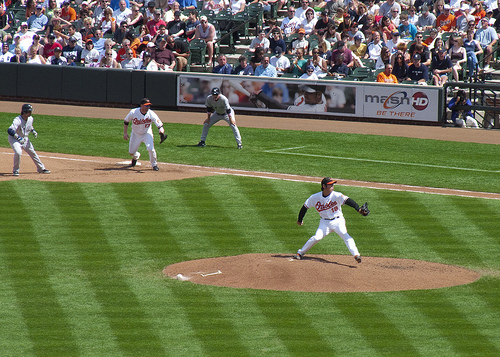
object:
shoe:
[153, 165, 159, 171]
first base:
[0, 142, 197, 187]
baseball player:
[123, 98, 166, 170]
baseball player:
[295, 175, 369, 262]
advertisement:
[176, 76, 437, 122]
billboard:
[176, 75, 440, 124]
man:
[446, 90, 479, 128]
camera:
[455, 96, 465, 102]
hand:
[455, 96, 460, 103]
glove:
[357, 202, 370, 216]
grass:
[0, 293, 497, 353]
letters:
[132, 117, 151, 128]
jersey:
[125, 108, 164, 134]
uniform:
[298, 191, 362, 255]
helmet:
[21, 103, 33, 116]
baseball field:
[0, 98, 497, 355]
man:
[376, 63, 398, 84]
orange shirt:
[378, 72, 398, 84]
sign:
[176, 75, 438, 124]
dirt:
[162, 252, 478, 293]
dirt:
[1, 143, 498, 198]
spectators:
[1, 1, 498, 107]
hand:
[203, 117, 210, 124]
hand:
[230, 120, 236, 127]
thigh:
[205, 114, 221, 127]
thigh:
[223, 113, 236, 124]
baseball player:
[195, 88, 242, 149]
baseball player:
[7, 104, 51, 177]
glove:
[160, 133, 169, 144]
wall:
[0, 64, 446, 123]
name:
[314, 202, 339, 212]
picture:
[0, 0, 500, 356]